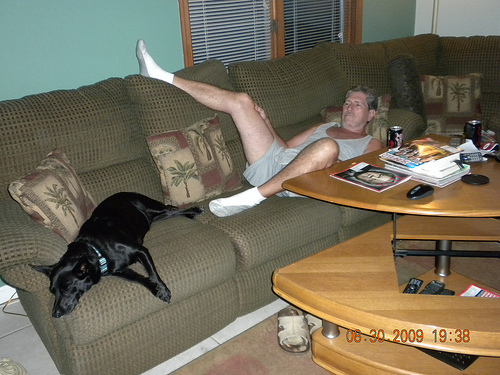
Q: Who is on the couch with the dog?
A: A man.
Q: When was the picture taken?
A: At night.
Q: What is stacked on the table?
A: Magazines.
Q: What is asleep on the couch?
A: Dog.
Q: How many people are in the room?
A: One.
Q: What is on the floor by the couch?
A: Sandals.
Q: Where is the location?
A: Living room.